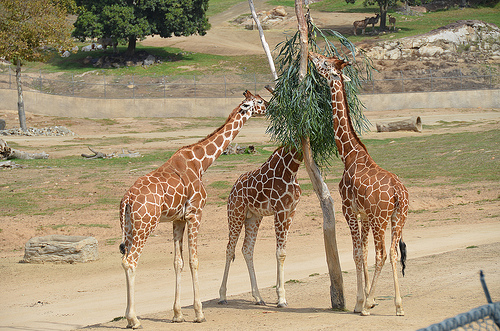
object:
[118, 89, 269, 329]
giraffes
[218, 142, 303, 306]
giraffes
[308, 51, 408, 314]
giraffes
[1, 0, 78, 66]
leaves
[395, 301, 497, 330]
fence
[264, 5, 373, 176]
limb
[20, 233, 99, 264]
rock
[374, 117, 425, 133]
pipe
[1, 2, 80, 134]
tree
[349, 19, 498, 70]
hill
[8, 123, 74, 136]
rock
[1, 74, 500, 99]
fence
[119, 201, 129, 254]
tail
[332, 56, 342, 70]
ear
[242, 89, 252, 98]
horn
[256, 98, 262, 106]
eye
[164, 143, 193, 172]
back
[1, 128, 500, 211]
grass